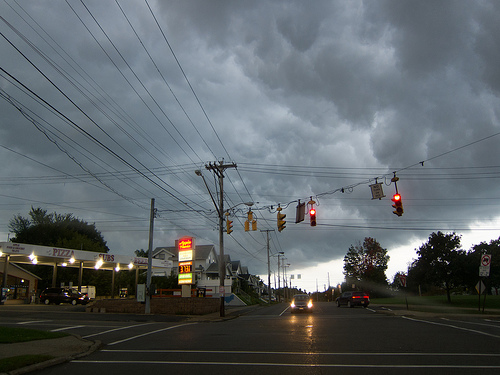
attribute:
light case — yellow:
[225, 220, 235, 234]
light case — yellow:
[242, 211, 257, 232]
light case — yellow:
[277, 213, 285, 231]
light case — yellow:
[252, 220, 258, 235]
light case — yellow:
[245, 222, 250, 232]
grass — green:
[368, 294, 498, 306]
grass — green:
[0, 325, 69, 370]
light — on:
[289, 298, 296, 310]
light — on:
[305, 299, 313, 314]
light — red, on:
[354, 296, 360, 299]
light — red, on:
[362, 294, 368, 301]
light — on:
[77, 294, 86, 304]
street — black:
[2, 294, 497, 370]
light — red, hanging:
[308, 208, 317, 215]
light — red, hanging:
[393, 195, 401, 201]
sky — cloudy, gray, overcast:
[1, 0, 499, 294]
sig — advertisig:
[176, 236, 196, 253]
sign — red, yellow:
[172, 238, 198, 269]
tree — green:
[34, 214, 93, 239]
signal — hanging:
[387, 190, 420, 227]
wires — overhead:
[176, 65, 215, 166]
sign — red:
[35, 241, 92, 264]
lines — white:
[158, 345, 180, 369]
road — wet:
[333, 328, 358, 346]